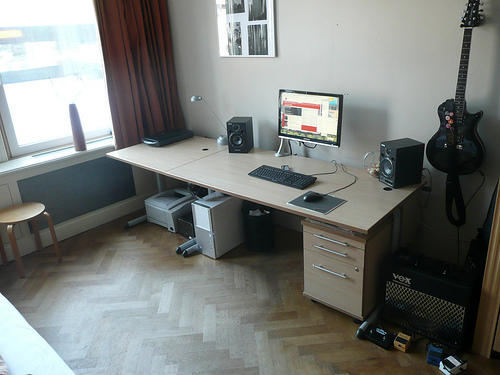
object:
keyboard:
[248, 156, 314, 191]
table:
[191, 144, 383, 237]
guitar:
[428, 1, 483, 178]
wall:
[348, 7, 427, 112]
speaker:
[226, 115, 254, 154]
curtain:
[87, 0, 190, 144]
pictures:
[217, 1, 279, 60]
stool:
[0, 197, 65, 282]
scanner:
[139, 127, 195, 146]